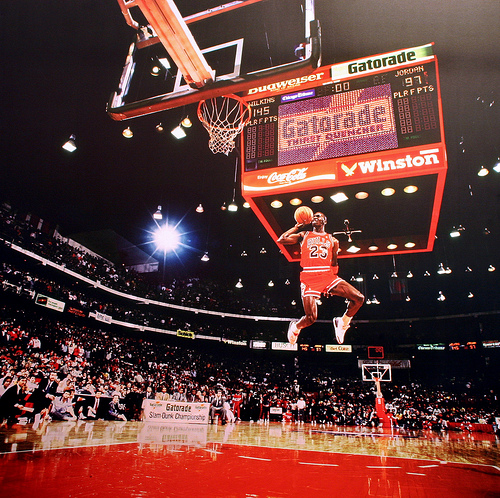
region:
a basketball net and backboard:
[108, 10, 318, 156]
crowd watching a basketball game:
[20, 231, 190, 461]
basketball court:
[35, 336, 477, 487]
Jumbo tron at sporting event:
[221, 72, 461, 262]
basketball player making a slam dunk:
[101, 51, 376, 457]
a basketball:
[290, 200, 312, 223]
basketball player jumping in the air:
[263, 200, 375, 346]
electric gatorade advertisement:
[273, 97, 398, 154]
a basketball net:
[188, 81, 253, 159]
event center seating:
[19, 191, 498, 447]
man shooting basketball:
[262, 191, 405, 382]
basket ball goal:
[318, 338, 438, 456]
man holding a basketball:
[250, 201, 370, 377]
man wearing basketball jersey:
[235, 180, 382, 362]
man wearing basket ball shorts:
[245, 176, 388, 381]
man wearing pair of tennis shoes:
[275, 185, 412, 410]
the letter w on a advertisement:
[210, 138, 468, 240]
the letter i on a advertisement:
[181, 133, 472, 232]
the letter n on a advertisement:
[228, 144, 466, 239]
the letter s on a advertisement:
[181, 138, 483, 253]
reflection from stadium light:
[146, 209, 217, 289]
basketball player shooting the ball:
[233, 209, 382, 315]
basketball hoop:
[345, 364, 413, 386]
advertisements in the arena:
[93, 307, 310, 364]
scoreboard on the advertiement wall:
[449, 333, 479, 358]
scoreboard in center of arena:
[252, 50, 473, 189]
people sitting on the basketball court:
[24, 385, 147, 422]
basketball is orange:
[293, 193, 318, 226]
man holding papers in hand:
[9, 396, 42, 418]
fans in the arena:
[30, 334, 135, 380]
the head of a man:
[309, 206, 331, 230]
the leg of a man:
[324, 272, 371, 319]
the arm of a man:
[273, 225, 303, 251]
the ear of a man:
[321, 216, 329, 227]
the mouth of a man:
[309, 217, 317, 226]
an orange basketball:
[289, 197, 320, 229]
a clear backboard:
[360, 360, 397, 384]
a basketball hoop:
[191, 85, 257, 157]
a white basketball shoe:
[328, 310, 355, 348]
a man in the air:
[266, 202, 368, 358]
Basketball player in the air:
[266, 200, 373, 361]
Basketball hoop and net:
[195, 90, 251, 155]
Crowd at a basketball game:
[56, 338, 132, 438]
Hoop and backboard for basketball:
[81, 21, 338, 161]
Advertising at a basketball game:
[130, 387, 220, 437]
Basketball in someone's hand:
[287, 202, 315, 229]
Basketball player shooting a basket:
[271, 190, 371, 360]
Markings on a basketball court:
[223, 430, 449, 495]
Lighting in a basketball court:
[60, 122, 197, 157]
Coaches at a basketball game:
[0, 366, 76, 448]